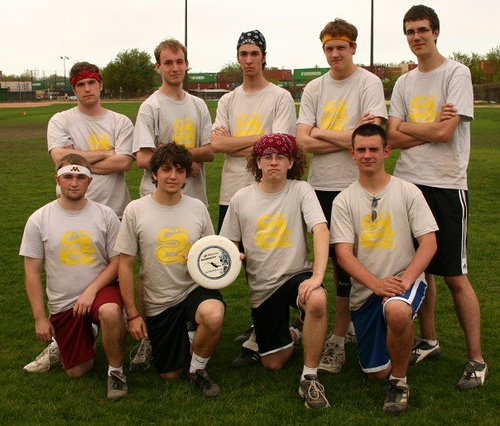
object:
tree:
[99, 46, 156, 99]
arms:
[311, 118, 382, 152]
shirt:
[113, 193, 218, 318]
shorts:
[48, 290, 122, 370]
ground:
[0, 134, 500, 425]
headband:
[56, 165, 90, 178]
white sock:
[301, 365, 319, 383]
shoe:
[456, 357, 486, 390]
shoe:
[406, 339, 442, 364]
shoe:
[382, 377, 410, 412]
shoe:
[297, 375, 332, 410]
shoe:
[129, 337, 156, 372]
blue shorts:
[350, 272, 426, 373]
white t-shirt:
[18, 199, 122, 317]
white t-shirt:
[216, 182, 327, 308]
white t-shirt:
[328, 176, 439, 312]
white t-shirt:
[46, 107, 134, 220]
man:
[329, 124, 439, 411]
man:
[216, 135, 333, 413]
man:
[382, 4, 489, 392]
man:
[113, 142, 226, 396]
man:
[18, 153, 130, 403]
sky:
[3, 5, 498, 81]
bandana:
[254, 133, 297, 158]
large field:
[1, 105, 498, 422]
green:
[1, 99, 498, 424]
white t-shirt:
[112, 194, 217, 317]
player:
[209, 31, 298, 232]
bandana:
[70, 70, 101, 87]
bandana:
[237, 29, 267, 51]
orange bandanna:
[321, 31, 355, 45]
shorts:
[144, 281, 226, 373]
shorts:
[250, 269, 327, 358]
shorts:
[407, 176, 467, 277]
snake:
[156, 228, 190, 265]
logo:
[59, 228, 95, 266]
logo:
[254, 211, 292, 250]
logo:
[360, 212, 396, 252]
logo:
[88, 132, 111, 151]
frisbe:
[187, 235, 244, 290]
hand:
[239, 252, 245, 260]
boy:
[45, 60, 132, 217]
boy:
[130, 38, 212, 209]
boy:
[294, 17, 393, 218]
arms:
[50, 146, 112, 168]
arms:
[135, 151, 198, 177]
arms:
[210, 134, 255, 153]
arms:
[296, 123, 344, 155]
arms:
[398, 115, 460, 143]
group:
[20, 4, 491, 417]